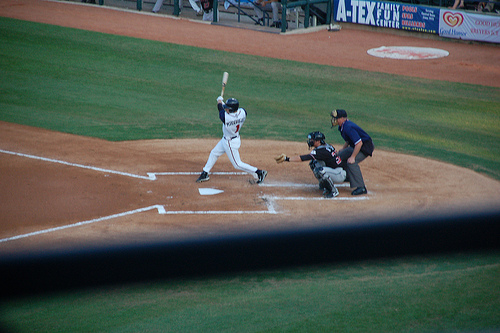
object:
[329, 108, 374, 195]
umpire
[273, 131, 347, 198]
catcher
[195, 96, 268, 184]
batter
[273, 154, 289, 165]
brown glove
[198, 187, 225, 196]
home plate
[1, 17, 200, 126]
grass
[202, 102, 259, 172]
uniform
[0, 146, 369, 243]
white markings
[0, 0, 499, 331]
baseball field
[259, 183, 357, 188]
lines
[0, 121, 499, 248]
dirt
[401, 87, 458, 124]
grass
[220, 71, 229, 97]
bat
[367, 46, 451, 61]
white circle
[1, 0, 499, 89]
red dirt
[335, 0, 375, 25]
a-tex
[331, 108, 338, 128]
facemask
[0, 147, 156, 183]
line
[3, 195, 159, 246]
line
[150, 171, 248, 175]
line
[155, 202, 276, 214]
line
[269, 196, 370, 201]
line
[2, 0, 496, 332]
field